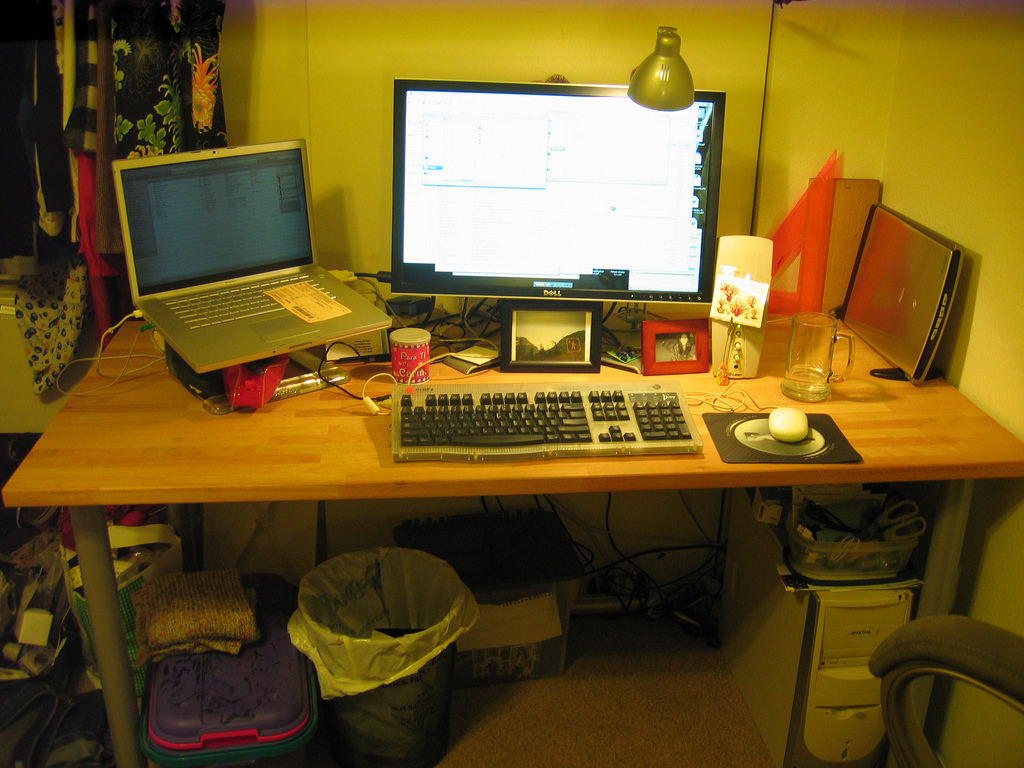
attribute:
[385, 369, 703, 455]
keyboard — silver, black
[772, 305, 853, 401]
mug — empty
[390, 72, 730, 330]
monitor — large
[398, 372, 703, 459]
keyboard — grey, black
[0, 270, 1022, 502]
table — brown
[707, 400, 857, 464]
mousepad — black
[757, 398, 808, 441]
mouse — white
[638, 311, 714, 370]
picture — red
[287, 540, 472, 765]
can — small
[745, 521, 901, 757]
computer — white , grey 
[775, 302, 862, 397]
glass — clear 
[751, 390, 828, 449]
mouse — white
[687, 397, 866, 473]
mousepad — black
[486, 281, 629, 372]
picture frame — black